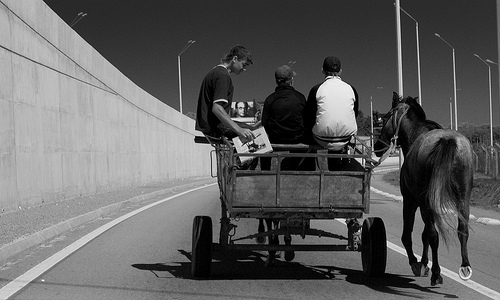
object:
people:
[194, 44, 258, 142]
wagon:
[186, 141, 392, 279]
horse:
[371, 90, 484, 290]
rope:
[373, 135, 396, 166]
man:
[258, 65, 314, 143]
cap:
[276, 61, 298, 80]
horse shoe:
[458, 265, 474, 280]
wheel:
[187, 213, 216, 279]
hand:
[238, 129, 258, 141]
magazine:
[233, 125, 273, 163]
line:
[82, 214, 122, 243]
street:
[129, 220, 160, 245]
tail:
[428, 136, 478, 250]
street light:
[67, 8, 92, 29]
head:
[272, 62, 298, 90]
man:
[302, 53, 365, 150]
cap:
[323, 52, 343, 74]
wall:
[1, 14, 175, 214]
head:
[220, 41, 258, 75]